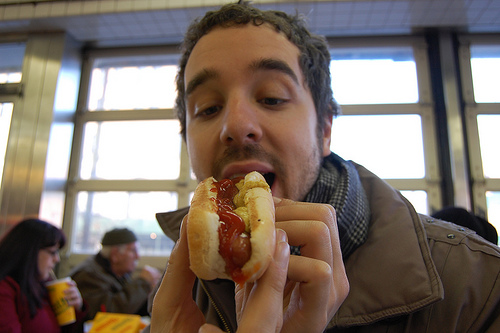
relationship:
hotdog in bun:
[205, 183, 252, 265] [178, 194, 219, 273]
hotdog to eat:
[205, 183, 252, 265] [224, 171, 272, 191]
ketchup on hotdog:
[207, 179, 262, 290] [205, 183, 252, 265]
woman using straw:
[7, 203, 75, 326] [49, 267, 59, 278]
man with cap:
[99, 222, 147, 293] [100, 226, 138, 247]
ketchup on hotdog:
[224, 214, 245, 239] [205, 183, 252, 265]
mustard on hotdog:
[233, 187, 249, 228] [205, 183, 252, 265]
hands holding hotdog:
[273, 199, 345, 309] [205, 183, 252, 265]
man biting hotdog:
[177, 23, 335, 206] [205, 183, 252, 265]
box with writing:
[92, 303, 147, 329] [107, 321, 132, 332]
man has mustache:
[177, 23, 335, 206] [217, 145, 267, 158]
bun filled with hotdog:
[178, 194, 219, 273] [205, 183, 252, 265]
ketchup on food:
[207, 179, 262, 290] [176, 169, 281, 242]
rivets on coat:
[445, 215, 462, 250] [404, 197, 443, 320]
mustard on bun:
[233, 187, 249, 228] [178, 194, 219, 273]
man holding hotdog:
[148, 0, 500, 332] [205, 183, 252, 265]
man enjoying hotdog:
[177, 23, 335, 206] [205, 183, 252, 265]